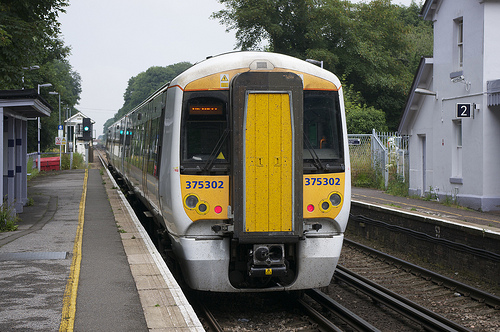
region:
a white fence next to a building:
[370, 130, 412, 184]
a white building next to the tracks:
[394, 0, 499, 211]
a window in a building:
[448, 116, 463, 185]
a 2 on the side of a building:
[451, 103, 476, 123]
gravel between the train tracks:
[234, 311, 298, 328]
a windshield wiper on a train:
[198, 123, 229, 174]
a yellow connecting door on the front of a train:
[233, 71, 304, 244]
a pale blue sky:
[54, 0, 269, 142]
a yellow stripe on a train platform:
[53, 160, 91, 328]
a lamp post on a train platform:
[34, 78, 54, 171]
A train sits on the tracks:
[103, 38, 355, 318]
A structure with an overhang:
[1, 90, 81, 238]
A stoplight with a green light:
[81, 118, 93, 144]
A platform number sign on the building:
[458, 98, 483, 123]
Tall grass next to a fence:
[353, 144, 381, 186]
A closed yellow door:
[234, 75, 306, 240]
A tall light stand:
[46, 90, 66, 172]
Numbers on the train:
[185, 180, 227, 191]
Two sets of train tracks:
[215, 290, 497, 330]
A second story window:
[448, 13, 464, 88]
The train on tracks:
[104, 54, 351, 330]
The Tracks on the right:
[334, 202, 499, 330]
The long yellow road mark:
[60, 166, 90, 330]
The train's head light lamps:
[176, 192, 353, 218]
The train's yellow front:
[172, 64, 349, 236]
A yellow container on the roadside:
[39, 155, 61, 172]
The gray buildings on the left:
[0, 82, 93, 222]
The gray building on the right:
[395, 3, 498, 214]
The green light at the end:
[84, 123, 89, 133]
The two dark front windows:
[182, 89, 344, 174]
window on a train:
[297, 83, 344, 176]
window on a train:
[182, 85, 237, 177]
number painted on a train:
[184, 178, 192, 192]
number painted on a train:
[190, 178, 198, 190]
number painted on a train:
[195, 178, 205, 188]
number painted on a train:
[202, 178, 211, 190]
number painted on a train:
[210, 179, 217, 187]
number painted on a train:
[215, 178, 226, 190]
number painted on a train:
[302, 175, 312, 186]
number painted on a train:
[309, 174, 317, 186]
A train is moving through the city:
[60, 18, 463, 318]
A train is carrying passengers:
[71, 25, 437, 322]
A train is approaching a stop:
[75, 15, 425, 326]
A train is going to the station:
[70, 30, 421, 326]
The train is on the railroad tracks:
[81, 32, 459, 319]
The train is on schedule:
[90, 37, 462, 317]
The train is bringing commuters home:
[80, 40, 460, 317]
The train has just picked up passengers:
[55, 20, 481, 308]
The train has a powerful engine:
[66, 40, 477, 326]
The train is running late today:
[95, 28, 481, 330]